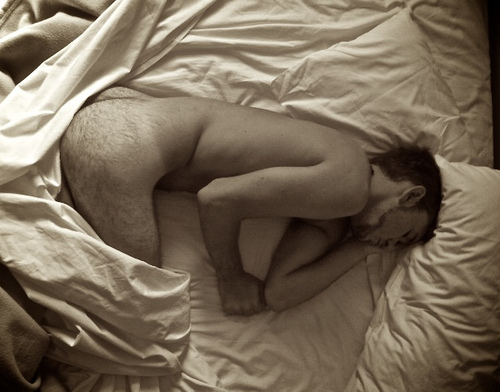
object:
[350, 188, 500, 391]
wrinkles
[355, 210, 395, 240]
beard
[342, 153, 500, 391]
pillow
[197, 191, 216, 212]
elbow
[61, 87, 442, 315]
naked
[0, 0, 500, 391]
sheets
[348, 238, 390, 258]
hand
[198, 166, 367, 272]
arm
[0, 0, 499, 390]
bed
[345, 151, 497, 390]
pillow case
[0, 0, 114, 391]
blanket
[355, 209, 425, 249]
face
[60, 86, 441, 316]
man